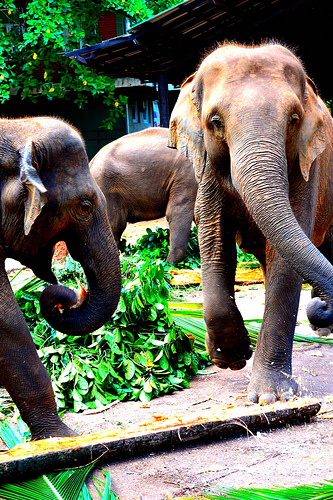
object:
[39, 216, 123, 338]
trunk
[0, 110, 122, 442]
elephant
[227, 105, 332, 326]
grey trunk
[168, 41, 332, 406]
elephant